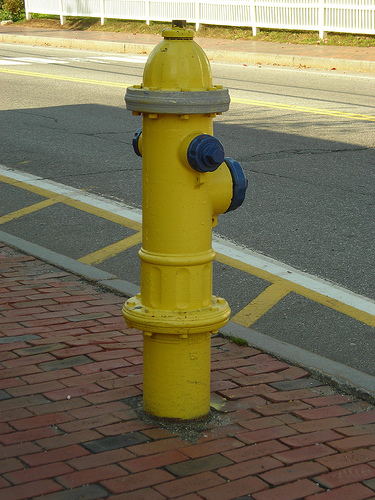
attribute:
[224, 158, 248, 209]
cap — blue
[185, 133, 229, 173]
lid — blue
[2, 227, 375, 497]
sidewalk — cobblestone, red, brick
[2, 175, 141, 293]
lines — yellow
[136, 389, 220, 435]
base — yellow, gray, eroded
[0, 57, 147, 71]
lines — white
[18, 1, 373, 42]
fence — white, wooden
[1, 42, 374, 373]
street — gray, asphalt, black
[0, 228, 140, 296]
curb — concrete, grey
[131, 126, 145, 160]
bolts — metal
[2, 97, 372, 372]
shadow — building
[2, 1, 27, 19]
bush — green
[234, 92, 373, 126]
line — yellow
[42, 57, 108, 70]
marks — white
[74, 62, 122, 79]
brink — dark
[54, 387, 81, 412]
spot — white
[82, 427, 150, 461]
brick — black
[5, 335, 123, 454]
bricks — red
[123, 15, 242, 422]
fire hydrant — yellow